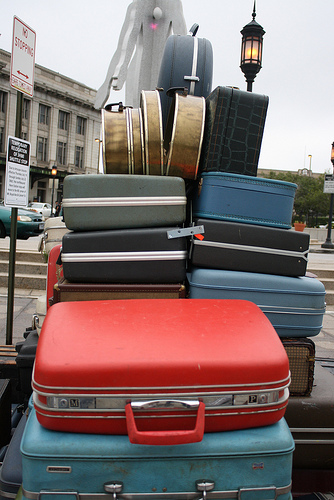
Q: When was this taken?
A: During the day.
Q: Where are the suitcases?
A: On the sidewalk.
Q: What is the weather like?
A: Cloudy.